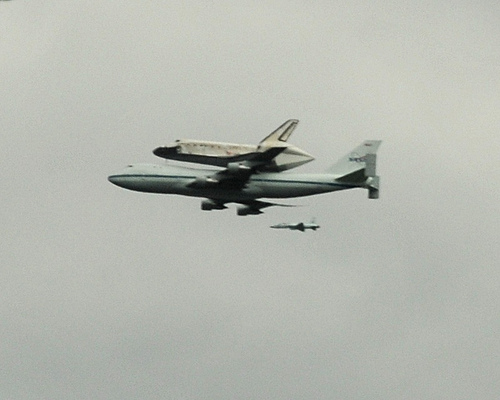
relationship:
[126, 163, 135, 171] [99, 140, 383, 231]
cockpit windows of plane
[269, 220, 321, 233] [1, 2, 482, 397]
plane flying in distance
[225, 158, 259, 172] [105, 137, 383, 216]
engine powering plane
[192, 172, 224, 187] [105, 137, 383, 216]
engine powering plane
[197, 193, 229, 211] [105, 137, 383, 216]
engine powering plane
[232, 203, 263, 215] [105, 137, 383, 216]
engine powering plane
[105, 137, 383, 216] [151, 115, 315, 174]
plane carrying plane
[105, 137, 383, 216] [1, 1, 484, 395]
plane flying in sky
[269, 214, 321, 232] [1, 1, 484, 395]
plane flying in sky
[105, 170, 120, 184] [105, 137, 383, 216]
nose belonging to plane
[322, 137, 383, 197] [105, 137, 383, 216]
tail attached to plane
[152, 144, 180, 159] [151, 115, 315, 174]
nose belonging to plane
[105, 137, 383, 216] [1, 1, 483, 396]
plane flying in air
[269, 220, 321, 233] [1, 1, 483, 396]
plane flying in air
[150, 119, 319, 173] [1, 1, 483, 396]
planes being transported in air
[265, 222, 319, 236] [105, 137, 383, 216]
airforce escorting plane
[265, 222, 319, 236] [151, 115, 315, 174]
airforce escorting plane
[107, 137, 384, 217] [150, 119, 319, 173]
airplane carrying planes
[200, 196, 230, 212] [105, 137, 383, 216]
turbine engine powering plane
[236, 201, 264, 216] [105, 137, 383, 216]
turbine engine powering plane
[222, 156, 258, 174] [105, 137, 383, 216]
turbine engine powering plane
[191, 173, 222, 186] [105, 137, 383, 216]
turbine engine powering plane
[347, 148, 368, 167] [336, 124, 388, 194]
insignia on tail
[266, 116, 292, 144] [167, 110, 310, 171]
part on plane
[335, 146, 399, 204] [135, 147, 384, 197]
part on plane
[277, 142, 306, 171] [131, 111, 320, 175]
part on plane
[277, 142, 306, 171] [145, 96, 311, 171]
part on plane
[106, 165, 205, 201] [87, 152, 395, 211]
part on plane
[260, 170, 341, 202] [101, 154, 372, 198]
part on plane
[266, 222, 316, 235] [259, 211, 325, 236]
part on plane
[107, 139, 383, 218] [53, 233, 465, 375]
airplane in grey sky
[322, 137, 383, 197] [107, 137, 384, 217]
tail on airplane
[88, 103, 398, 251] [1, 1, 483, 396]
planes in air